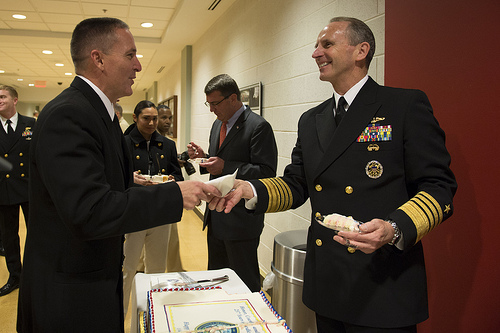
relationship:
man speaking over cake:
[13, 16, 223, 332] [142, 280, 294, 331]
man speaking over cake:
[207, 16, 458, 332] [142, 280, 294, 331]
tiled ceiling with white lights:
[3, 4, 178, 94] [9, 10, 72, 89]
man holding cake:
[207, 16, 458, 332] [318, 212, 362, 233]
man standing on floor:
[207, 16, 458, 332] [1, 223, 220, 271]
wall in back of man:
[377, 3, 484, 330] [207, 16, 458, 332]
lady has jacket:
[122, 99, 184, 332] [120, 126, 193, 232]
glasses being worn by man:
[204, 93, 233, 108] [188, 72, 279, 290]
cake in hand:
[323, 212, 360, 229] [321, 213, 399, 251]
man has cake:
[187, 74, 279, 292] [148, 172, 173, 182]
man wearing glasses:
[187, 74, 279, 292] [201, 95, 235, 103]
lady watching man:
[122, 91, 183, 271] [207, 16, 458, 332]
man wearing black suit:
[15, 29, 210, 328] [20, 82, 180, 332]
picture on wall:
[240, 81, 262, 110] [139, 0, 383, 291]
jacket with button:
[246, 75, 458, 328] [313, 210, 322, 220]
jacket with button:
[246, 75, 458, 328] [316, 179, 365, 199]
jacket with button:
[269, 71, 492, 292] [346, 243, 355, 254]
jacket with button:
[246, 75, 458, 328] [343, 184, 357, 198]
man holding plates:
[136, 104, 186, 273] [176, 140, 234, 192]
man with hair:
[207, 16, 458, 332] [324, 6, 434, 75]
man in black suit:
[207, 16, 458, 332] [15, 76, 184, 332]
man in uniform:
[207, 16, 458, 332] [244, 72, 458, 331]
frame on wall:
[235, 81, 270, 118] [202, 0, 312, 85]